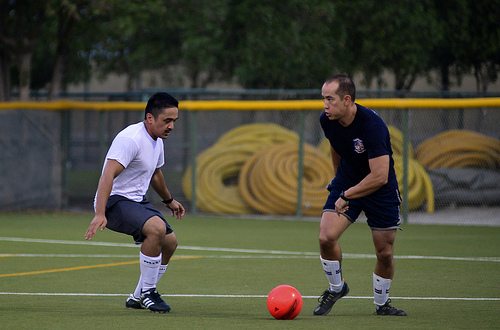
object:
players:
[79, 92, 186, 317]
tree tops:
[1, 1, 498, 94]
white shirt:
[93, 122, 166, 203]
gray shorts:
[102, 190, 179, 245]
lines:
[3, 247, 77, 286]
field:
[1, 205, 487, 329]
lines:
[0, 288, 497, 305]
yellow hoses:
[180, 115, 498, 227]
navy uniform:
[319, 102, 403, 230]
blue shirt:
[318, 104, 398, 198]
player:
[312, 77, 412, 318]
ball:
[266, 282, 303, 319]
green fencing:
[25, 99, 498, 193]